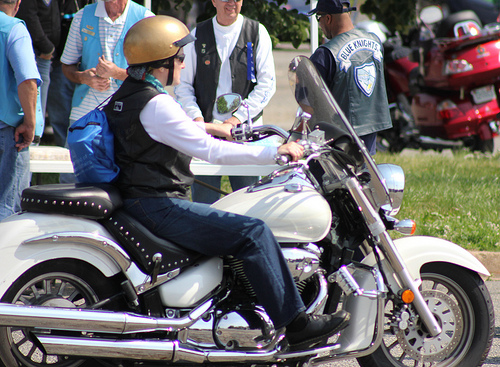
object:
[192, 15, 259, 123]
vest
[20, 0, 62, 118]
people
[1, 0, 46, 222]
people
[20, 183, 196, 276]
seat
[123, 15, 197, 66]
helmet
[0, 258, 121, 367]
wheel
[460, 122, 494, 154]
wheel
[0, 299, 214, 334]
pipe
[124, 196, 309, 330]
jeans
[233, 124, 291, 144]
bar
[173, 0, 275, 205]
people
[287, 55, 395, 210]
windshield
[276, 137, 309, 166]
bars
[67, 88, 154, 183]
backpack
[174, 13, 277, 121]
shirt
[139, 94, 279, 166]
shirt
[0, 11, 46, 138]
vest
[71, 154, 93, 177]
lettering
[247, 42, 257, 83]
ribbon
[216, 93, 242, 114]
sideview mirror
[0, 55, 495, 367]
bike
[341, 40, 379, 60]
biker-gang name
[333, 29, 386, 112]
back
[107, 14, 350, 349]
cyclist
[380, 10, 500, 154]
motorcycle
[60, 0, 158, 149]
person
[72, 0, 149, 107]
vest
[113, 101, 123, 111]
emblem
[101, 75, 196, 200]
jacket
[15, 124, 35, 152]
hand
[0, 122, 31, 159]
hip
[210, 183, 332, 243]
tank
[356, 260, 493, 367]
wheel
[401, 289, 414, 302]
reflector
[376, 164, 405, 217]
headlight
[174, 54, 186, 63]
sunglasses